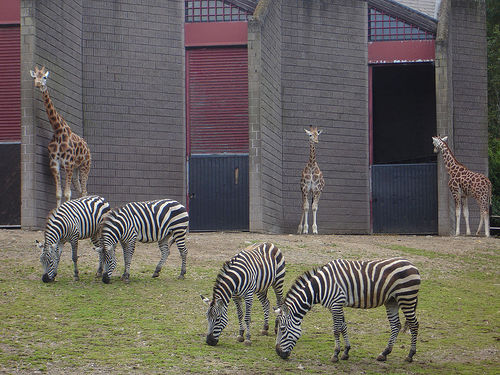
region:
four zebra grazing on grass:
[33, 188, 429, 370]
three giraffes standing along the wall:
[29, 53, 496, 241]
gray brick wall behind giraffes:
[22, 2, 489, 236]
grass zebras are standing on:
[8, 249, 488, 369]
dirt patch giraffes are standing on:
[7, 221, 490, 258]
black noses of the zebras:
[40, 271, 288, 363]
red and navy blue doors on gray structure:
[1, 23, 248, 233]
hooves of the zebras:
[43, 259, 414, 366]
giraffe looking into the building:
[430, 131, 495, 235]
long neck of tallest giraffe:
[45, 86, 62, 128]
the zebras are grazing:
[45, 198, 420, 367]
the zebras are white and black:
[43, 194, 419, 361]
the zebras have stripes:
[46, 188, 420, 362]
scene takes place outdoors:
[1, 0, 497, 371]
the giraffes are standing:
[30, 62, 492, 234]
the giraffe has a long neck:
[41, 88, 65, 133]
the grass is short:
[0, 228, 499, 373]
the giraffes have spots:
[31, 63, 494, 235]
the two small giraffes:
[294, 123, 490, 235]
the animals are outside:
[0, 3, 498, 373]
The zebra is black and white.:
[34, 185, 113, 290]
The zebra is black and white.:
[96, 194, 204, 300]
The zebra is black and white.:
[197, 228, 286, 353]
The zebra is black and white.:
[268, 252, 432, 368]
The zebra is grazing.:
[196, 236, 297, 358]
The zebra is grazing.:
[87, 196, 201, 287]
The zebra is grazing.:
[27, 191, 114, 286]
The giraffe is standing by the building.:
[16, 43, 109, 240]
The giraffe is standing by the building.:
[335, 0, 498, 251]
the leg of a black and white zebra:
[68, 234, 81, 281]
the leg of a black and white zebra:
[93, 228, 107, 276]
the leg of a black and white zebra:
[120, 236, 136, 281]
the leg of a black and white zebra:
[152, 234, 169, 276]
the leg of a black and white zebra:
[175, 221, 189, 281]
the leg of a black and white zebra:
[232, 296, 244, 341]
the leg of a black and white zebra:
[241, 289, 258, 346]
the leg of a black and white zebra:
[256, 282, 273, 334]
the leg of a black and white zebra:
[275, 278, 285, 303]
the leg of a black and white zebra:
[329, 296, 344, 364]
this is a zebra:
[260, 256, 443, 356]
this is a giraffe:
[414, 112, 493, 255]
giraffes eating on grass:
[255, 245, 443, 371]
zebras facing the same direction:
[34, 165, 471, 374]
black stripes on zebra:
[323, 260, 405, 299]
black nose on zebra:
[268, 337, 348, 347]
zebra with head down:
[250, 274, 325, 358]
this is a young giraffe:
[284, 106, 343, 253]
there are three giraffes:
[12, 40, 499, 262]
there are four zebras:
[27, 160, 448, 373]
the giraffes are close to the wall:
[18, 48, 498, 248]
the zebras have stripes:
[25, 179, 468, 371]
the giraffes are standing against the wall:
[12, 45, 499, 245]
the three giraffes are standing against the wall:
[15, 46, 499, 255]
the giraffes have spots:
[22, 53, 498, 263]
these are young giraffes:
[278, 109, 498, 245]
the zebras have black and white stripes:
[32, 160, 447, 374]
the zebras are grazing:
[2, 155, 432, 373]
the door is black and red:
[170, 21, 287, 233]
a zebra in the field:
[320, 272, 464, 341]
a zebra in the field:
[192, 253, 276, 328]